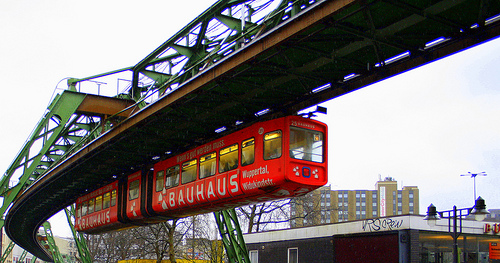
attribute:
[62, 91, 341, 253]
train — red, car, traveling, track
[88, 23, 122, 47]
sky — blue, overcast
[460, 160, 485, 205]
antenna — metal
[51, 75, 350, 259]
railcar — attached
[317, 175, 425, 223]
building — tan, tall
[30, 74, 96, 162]
scaffolding — green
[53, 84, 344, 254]
car — red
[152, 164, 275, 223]
paint — spray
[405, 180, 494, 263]
pole — light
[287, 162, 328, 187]
sign — red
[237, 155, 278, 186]
writing — white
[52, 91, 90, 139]
metal — green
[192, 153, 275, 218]
letter — white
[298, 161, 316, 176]
square — blue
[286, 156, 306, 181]
symbol — white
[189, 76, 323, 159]
track — silver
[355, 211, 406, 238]
graffiti — black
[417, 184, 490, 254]
lamp — street